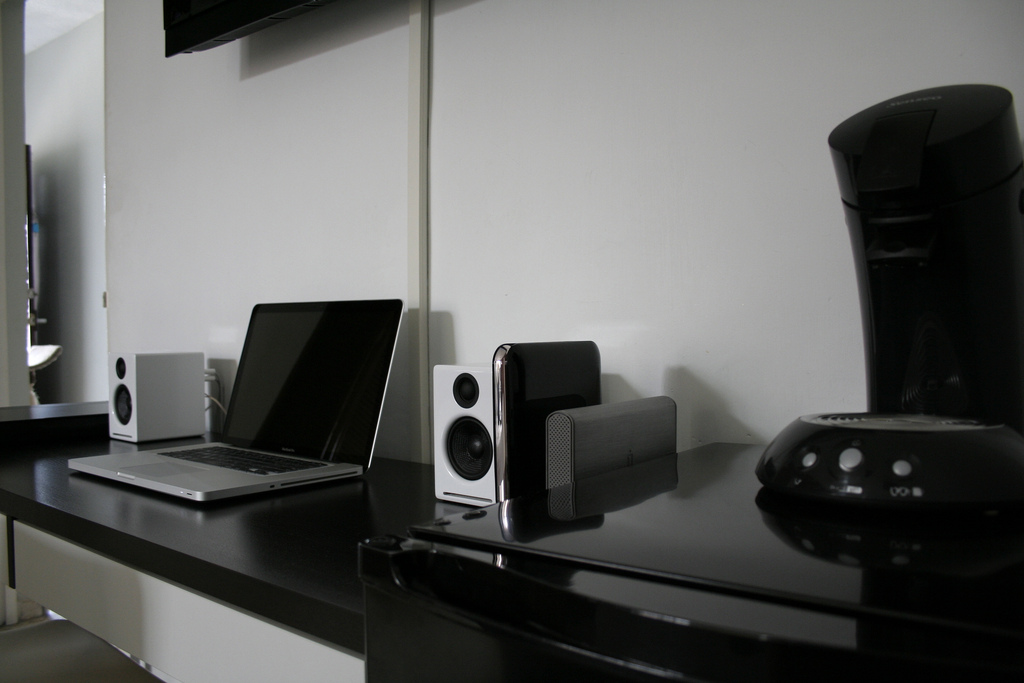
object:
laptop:
[68, 296, 410, 509]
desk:
[0, 432, 488, 682]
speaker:
[432, 363, 504, 507]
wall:
[468, 40, 693, 201]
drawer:
[9, 518, 363, 682]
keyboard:
[156, 444, 329, 476]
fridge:
[361, 443, 1024, 682]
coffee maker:
[753, 84, 1022, 574]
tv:
[164, 0, 304, 59]